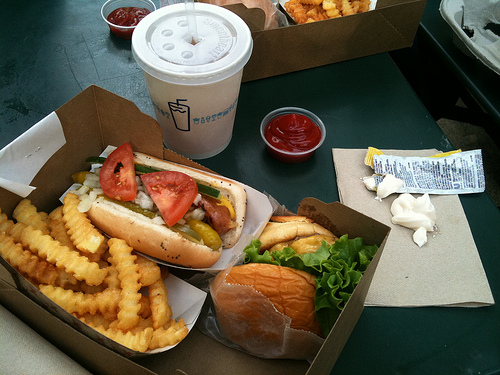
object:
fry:
[107, 238, 141, 328]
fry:
[87, 326, 152, 351]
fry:
[62, 191, 105, 253]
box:
[241, 1, 423, 82]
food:
[284, 0, 370, 23]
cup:
[260, 107, 326, 164]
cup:
[145, 70, 246, 160]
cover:
[131, 0, 254, 87]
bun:
[214, 263, 315, 359]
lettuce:
[243, 234, 379, 312]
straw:
[185, 0, 196, 44]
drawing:
[167, 99, 190, 131]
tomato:
[99, 142, 136, 201]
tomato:
[139, 171, 197, 226]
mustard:
[216, 196, 235, 219]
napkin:
[332, 147, 493, 307]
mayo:
[391, 192, 437, 246]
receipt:
[0, 110, 68, 198]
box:
[0, 84, 390, 375]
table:
[0, 51, 499, 374]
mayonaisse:
[373, 150, 483, 194]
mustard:
[364, 146, 462, 191]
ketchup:
[264, 113, 321, 152]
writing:
[194, 98, 238, 123]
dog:
[74, 143, 247, 269]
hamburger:
[210, 237, 366, 359]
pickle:
[86, 156, 220, 199]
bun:
[86, 152, 246, 268]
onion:
[139, 191, 153, 208]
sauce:
[375, 174, 403, 202]